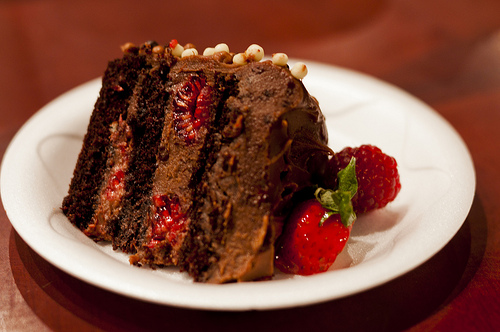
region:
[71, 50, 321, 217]
Slice of chocolate cake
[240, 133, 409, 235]
Fruit next to cake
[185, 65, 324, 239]
frosting on top of cake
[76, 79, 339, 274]
Chocolate cake on a plate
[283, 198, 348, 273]
strawberry on top of cake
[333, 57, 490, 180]
white plate on the table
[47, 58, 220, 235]
Chocolate cake with frosting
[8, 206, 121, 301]
Brown table and white plate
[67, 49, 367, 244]
Chocolate slice of cake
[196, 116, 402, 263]
cake and fruit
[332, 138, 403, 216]
red rasberry on white plate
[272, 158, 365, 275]
sliced strawberry on white plate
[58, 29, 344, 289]
slice of chocolate cake with nuts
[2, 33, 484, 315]
slice of chocolate cake in round white bowl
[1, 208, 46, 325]
corner of wooden table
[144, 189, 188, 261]
red sauce inside of cake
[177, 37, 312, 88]
nuts on top of chcolate cake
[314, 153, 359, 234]
green leafs on top of sliced strawberry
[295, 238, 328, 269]
black strawberry seeds in skin of strawberry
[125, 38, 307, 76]
nuts on ecterior of cake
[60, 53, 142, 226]
layer of chocolate cake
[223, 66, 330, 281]
chocolate icing on cake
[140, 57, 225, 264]
strawberry and chocolate layer in cake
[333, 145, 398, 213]
raspberry on white dish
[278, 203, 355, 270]
cut strawberry on white dish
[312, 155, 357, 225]
green leaves and stem on strawberry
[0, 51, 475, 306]
white ceramic dish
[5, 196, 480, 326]
shadow from dish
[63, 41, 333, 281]
pice of strawberry chocolate cake on white dish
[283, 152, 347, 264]
strawberries on top of a cake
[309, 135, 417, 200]
raspberry on top of cake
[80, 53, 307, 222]
Three layer chocolate cake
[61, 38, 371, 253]
chocolate cake on a plate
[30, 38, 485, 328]
Plate with chocolate cake on it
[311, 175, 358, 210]
green leaf on a raspberry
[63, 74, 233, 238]
Frosting in the cake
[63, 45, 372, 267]
plate of chocolate cake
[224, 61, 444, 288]
cake with fruit on top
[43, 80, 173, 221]
slice of chocolate cake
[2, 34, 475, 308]
cake on white plate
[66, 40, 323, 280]
cut slice of cake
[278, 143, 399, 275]
two pieces of fruit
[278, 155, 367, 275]
green leaf on strawberry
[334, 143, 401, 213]
red round rasberry behind leaf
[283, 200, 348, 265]
light reflection on red skin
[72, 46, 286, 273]
chocolate cake with layers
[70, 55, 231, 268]
three layers of cake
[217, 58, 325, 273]
chocolate frosting of cake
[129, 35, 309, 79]
decorations on side of cake